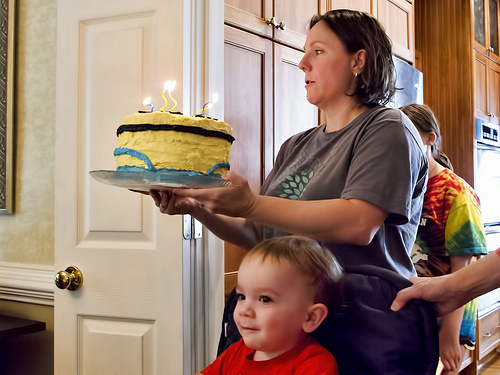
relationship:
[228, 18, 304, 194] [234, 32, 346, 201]
door on cabinet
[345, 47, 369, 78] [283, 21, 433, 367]
ear on woman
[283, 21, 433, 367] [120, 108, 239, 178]
woman holding cake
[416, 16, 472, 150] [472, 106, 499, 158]
cabinets in between over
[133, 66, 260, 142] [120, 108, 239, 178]
candles on cake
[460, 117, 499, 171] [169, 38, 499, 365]
oven in kitchen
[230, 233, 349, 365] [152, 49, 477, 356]
baby having birthday